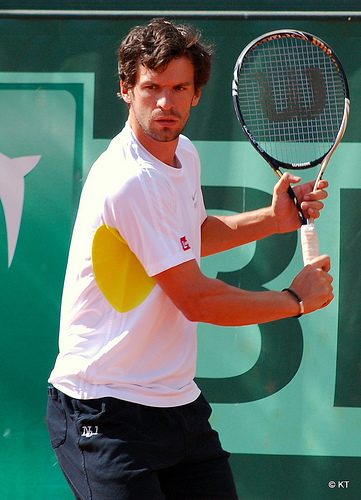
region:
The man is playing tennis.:
[32, 18, 348, 499]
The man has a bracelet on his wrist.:
[272, 280, 317, 325]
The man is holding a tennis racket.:
[225, 26, 349, 301]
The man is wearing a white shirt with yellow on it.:
[49, 138, 242, 415]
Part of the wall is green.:
[10, 285, 43, 373]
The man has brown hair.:
[103, 16, 217, 148]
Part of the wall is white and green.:
[1, 131, 51, 279]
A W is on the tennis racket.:
[249, 60, 334, 129]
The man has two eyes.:
[136, 70, 192, 97]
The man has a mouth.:
[145, 107, 185, 132]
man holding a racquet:
[187, 22, 346, 383]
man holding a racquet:
[67, 34, 343, 492]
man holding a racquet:
[105, 31, 352, 264]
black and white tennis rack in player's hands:
[232, 29, 350, 308]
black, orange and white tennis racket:
[232, 28, 350, 254]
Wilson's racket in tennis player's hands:
[232, 28, 351, 325]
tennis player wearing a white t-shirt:
[45, 16, 349, 497]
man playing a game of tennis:
[5, 8, 354, 498]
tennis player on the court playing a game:
[39, 13, 353, 496]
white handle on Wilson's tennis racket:
[301, 223, 322, 270]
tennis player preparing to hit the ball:
[43, 15, 352, 497]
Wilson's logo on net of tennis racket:
[246, 62, 327, 122]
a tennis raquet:
[235, 27, 349, 264]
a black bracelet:
[279, 284, 303, 321]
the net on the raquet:
[246, 49, 337, 149]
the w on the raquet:
[255, 68, 326, 121]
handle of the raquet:
[299, 223, 316, 260]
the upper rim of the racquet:
[230, 25, 348, 168]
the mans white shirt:
[51, 125, 203, 405]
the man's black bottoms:
[41, 377, 238, 496]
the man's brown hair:
[118, 28, 208, 83]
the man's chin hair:
[146, 125, 182, 141]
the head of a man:
[113, 11, 216, 139]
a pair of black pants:
[46, 378, 242, 498]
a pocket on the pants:
[42, 384, 71, 451]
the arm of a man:
[108, 178, 296, 328]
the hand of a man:
[287, 251, 337, 315]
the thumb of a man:
[273, 167, 302, 192]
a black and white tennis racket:
[227, 24, 353, 270]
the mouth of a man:
[151, 111, 177, 130]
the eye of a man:
[142, 76, 162, 96]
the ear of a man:
[187, 85, 204, 109]